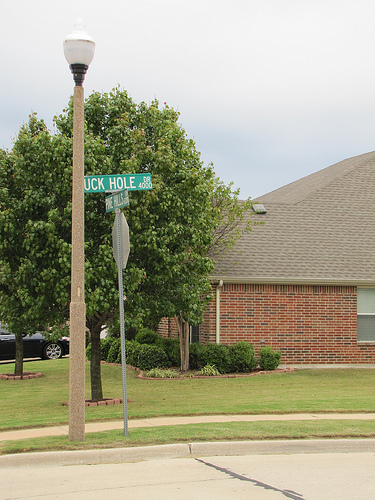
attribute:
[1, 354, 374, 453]
lawn — green, mowed, treamed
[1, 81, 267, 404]
tree — green, tall, large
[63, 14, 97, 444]
lamp post — very tall, tall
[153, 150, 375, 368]
house — brick, red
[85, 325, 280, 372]
bushes — green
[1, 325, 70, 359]
car — black, parked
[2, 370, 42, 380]
bricks — red, brick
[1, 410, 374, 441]
sidewalk — cement, gray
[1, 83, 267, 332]
leaves — green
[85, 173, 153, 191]
sign — green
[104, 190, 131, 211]
sign — green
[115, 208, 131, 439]
sign post — metal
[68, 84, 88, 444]
post — brown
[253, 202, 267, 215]
skylight — small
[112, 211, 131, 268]
stop sign — silver, metal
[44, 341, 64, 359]
car tire — rubber, metal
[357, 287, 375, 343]
window — glass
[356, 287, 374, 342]
trim — white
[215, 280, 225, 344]
gutter downspout — metal, white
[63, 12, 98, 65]
bulb — white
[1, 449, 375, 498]
road — clear